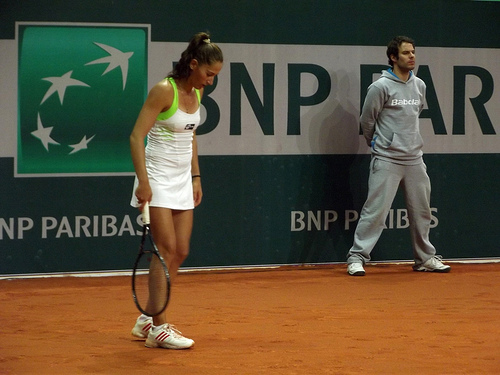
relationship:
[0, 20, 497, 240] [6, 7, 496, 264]
advertisement on wall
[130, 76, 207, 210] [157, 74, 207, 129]
dress has straps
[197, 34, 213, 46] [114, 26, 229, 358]
scurnchie on woman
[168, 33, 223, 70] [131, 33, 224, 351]
hair on woman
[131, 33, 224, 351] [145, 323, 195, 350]
woman has shoe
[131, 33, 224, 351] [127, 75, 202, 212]
woman has dress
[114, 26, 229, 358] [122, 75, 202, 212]
woman wears dress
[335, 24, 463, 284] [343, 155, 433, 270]
man wears pants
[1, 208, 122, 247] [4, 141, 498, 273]
letter on wall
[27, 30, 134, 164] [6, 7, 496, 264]
white stars on wall